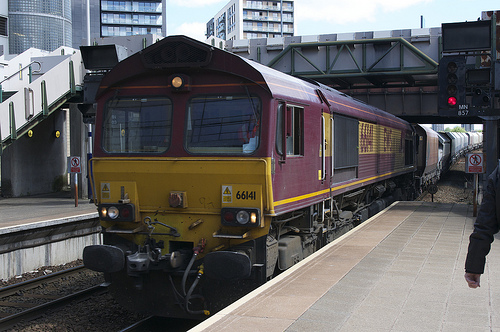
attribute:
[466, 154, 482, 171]
street sign — red, white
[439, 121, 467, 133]
leaves — green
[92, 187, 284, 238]
headlight — round 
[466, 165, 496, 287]
sleeve — dark, long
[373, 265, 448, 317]
stone tiles — grey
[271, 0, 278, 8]
window — tall, white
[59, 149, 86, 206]
sign post — white, orange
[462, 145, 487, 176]
warning sign — metal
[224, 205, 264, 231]
headlight — round, shiny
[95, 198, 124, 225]
headlight — round, shiny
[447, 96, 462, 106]
light — red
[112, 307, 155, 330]
train track — metal, brown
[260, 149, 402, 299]
broadsection — yellow